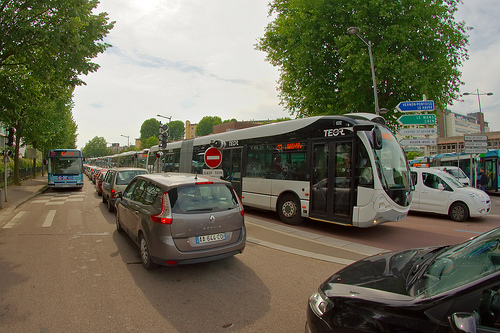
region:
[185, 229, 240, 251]
The license plate is black and white with blue on both sides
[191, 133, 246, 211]
The sign is red with a white rectangle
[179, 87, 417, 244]
A white and black bus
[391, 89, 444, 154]
A post has a blue, green and two white signs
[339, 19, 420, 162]
A grey light post beside the street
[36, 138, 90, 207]
A blue bus with an orange electric sign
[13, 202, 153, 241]
A street crossing sign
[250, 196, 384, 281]
A grey cement divider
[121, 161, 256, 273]
A grey hatchback with its brake lights on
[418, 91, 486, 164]
An advertisement on a cream colored building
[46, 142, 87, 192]
A blue bus front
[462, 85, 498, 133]
A double sided street light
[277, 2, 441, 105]
A green leafy tree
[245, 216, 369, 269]
White lines on a road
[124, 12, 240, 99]
A bright cloudy sky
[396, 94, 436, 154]
A group of street signs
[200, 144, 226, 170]
A no entry sign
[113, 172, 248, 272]
A grey mini van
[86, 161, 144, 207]
A long line of cars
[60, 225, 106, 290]
Stains on the roadway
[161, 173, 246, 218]
Back window of brown suv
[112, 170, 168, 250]
Left side of brown SUV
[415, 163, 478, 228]
Passenger side door of white auto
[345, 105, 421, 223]
Front windshield of bus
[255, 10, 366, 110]
Tall tree on side of street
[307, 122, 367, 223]
Entrance/exit door to bus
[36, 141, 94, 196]
Front of light blue bus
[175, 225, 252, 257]
License plate on back of brown SUV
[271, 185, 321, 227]
Right front wheel of bus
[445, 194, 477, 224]
Right front wheel of white auto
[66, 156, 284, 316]
VEHICLE IS SILVER AND COMPACT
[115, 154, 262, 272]
VEHICLE IS SILVER AND COMPACT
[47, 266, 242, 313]
the road is grey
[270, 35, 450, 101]
the trees are green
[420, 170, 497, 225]
the car is white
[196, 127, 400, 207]
the bus has passengers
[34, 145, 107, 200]
the bus is blue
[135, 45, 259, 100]
there are clouds in the sky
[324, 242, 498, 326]
the car is black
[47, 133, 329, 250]
there is traffic on the road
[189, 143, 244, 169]
the sign says says do not enter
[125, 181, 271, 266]
the car is a volwaks wagen